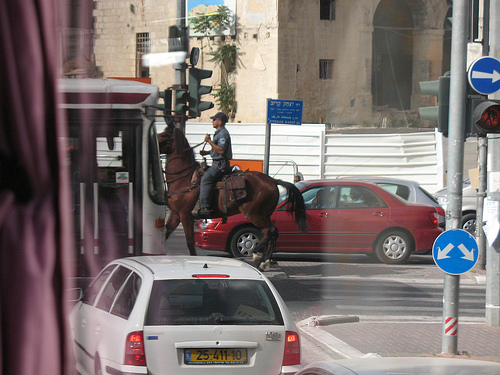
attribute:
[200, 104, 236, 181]
man — on horseback, mounted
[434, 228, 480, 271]
sign — round, blue, metal, traffic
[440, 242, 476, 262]
arrows — white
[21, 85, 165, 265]
bus — white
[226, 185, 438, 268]
car — red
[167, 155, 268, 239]
horse — brown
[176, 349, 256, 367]
license plate — yellow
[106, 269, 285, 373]
car — white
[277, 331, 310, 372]
light — brake, red, tail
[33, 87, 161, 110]
stripe — red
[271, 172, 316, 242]
tail — black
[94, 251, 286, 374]
station wagon — white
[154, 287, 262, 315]
window — black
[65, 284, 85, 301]
mirror — sidevview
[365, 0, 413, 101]
opening — arched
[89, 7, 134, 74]
wall — concrete, block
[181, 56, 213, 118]
signal — electric, traffic, traffic control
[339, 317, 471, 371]
sidewalk — brick, paved